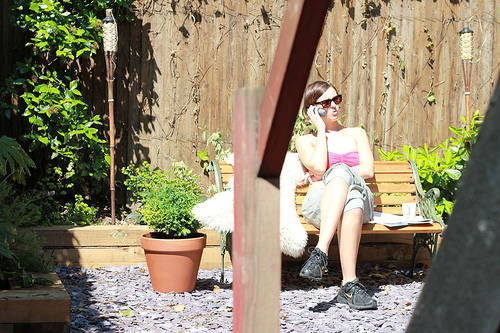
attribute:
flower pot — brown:
[137, 235, 202, 292]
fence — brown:
[76, 4, 498, 238]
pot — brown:
[125, 217, 221, 290]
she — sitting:
[292, 80, 379, 312]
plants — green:
[8, 12, 142, 239]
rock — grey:
[157, 321, 172, 328]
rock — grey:
[189, 289, 203, 296]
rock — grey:
[126, 299, 136, 304]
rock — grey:
[221, 310, 233, 318]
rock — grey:
[290, 319, 304, 326]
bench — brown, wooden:
[210, 155, 443, 293]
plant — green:
[120, 163, 210, 239]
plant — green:
[118, 149, 201, 236]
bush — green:
[117, 158, 200, 234]